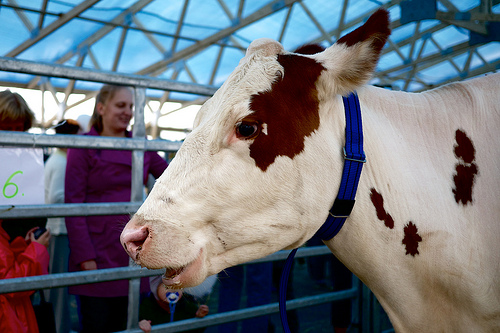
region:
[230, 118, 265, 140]
The eye of the cow.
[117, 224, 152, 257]
The nose of the cow.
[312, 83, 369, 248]
The blue collar on the cow.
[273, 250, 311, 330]
The leash part of the blue collar that is on the cow's neck.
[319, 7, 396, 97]
The right ear of the cow.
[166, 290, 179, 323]
The pacifier of the baby standing next to the gate.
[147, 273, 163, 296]
The hat on the baby.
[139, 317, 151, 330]
The left hand of the baby.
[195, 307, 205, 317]
The right hand of the baby.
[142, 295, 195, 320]
The black jacket the baby is wearing.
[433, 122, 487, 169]
this is a spot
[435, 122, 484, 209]
these are spots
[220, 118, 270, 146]
this is an eye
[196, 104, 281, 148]
this is a cow eye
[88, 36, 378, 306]
this is a head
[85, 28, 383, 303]
this is a cows head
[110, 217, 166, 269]
this is a nose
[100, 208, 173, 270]
this is a cow's nose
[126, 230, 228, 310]
this is a mouth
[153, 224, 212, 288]
this is a cows mouth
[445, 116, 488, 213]
the cow has brown spots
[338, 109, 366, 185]
the collar is blue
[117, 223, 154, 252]
the nose is pink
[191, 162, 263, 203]
the cow is white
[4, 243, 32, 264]
the coat is red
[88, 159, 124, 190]
the coat is purple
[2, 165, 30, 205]
the number is green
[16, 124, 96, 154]
the gate is silver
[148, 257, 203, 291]
the cows mouth is open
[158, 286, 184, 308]
the kid has a pacifier in its mouth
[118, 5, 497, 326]
A brown and white cow.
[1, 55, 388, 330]
A gray bar fence.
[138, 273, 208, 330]
A baby with a pacifier.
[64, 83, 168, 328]
A lady wearing purple.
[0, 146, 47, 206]
A sign on the fence.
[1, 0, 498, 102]
A blue metal ceiling.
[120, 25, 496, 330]
A cow with a collar.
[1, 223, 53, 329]
A kid with a camera.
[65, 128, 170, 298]
A purple jacket on a lady.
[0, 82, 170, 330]
People at an event.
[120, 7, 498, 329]
Cow looking straight ahead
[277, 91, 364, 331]
The collar is blue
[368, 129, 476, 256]
Brown spots on fur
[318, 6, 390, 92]
Ear is facing backwards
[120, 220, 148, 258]
Cow's nose is pink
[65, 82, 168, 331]
A woman is smiling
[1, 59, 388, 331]
Bars made of metal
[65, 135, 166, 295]
The shirt is purple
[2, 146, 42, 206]
The sign is white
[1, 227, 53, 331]
Someone holding a phone